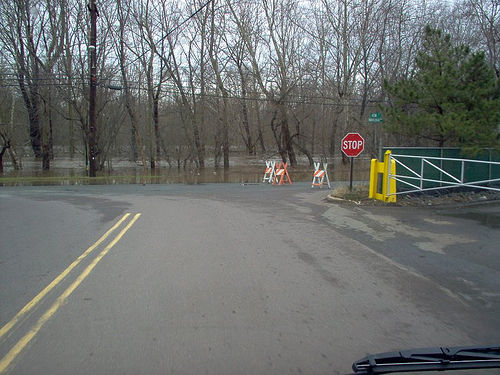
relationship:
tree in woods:
[161, 4, 251, 165] [1, 4, 499, 181]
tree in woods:
[315, 0, 365, 163] [8, 1, 498, 162]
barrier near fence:
[356, 141, 401, 208] [203, 122, 493, 219]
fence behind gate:
[375, 142, 497, 184] [382, 152, 497, 199]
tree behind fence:
[373, 22, 489, 154] [382, 144, 498, 199]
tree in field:
[315, 0, 365, 163] [198, 147, 256, 178]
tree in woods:
[373, 22, 489, 154] [8, 1, 498, 162]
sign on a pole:
[337, 130, 368, 160] [348, 154, 358, 188]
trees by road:
[84, 0, 284, 178] [146, 169, 363, 362]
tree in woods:
[1, 0, 74, 173] [1, 4, 499, 181]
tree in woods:
[161, 4, 222, 168] [10, 5, 388, 135]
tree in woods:
[137, 1, 167, 170] [9, 9, 366, 172]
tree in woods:
[373, 22, 489, 154] [297, 4, 499, 159]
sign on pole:
[366, 112, 387, 122] [372, 123, 378, 164]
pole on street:
[372, 123, 378, 164] [2, 189, 499, 369]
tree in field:
[161, 4, 251, 165] [0, 0, 496, 178]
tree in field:
[229, 0, 312, 167] [0, 0, 496, 178]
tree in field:
[373, 22, 489, 154] [226, 7, 497, 161]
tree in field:
[373, 22, 489, 154] [238, 12, 499, 169]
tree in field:
[283, 11, 499, 153] [276, 17, 491, 166]